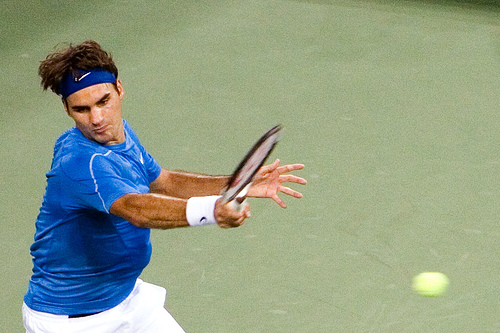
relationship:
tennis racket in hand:
[220, 123, 283, 213] [216, 197, 251, 229]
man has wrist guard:
[21, 37, 307, 333] [186, 193, 224, 227]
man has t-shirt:
[21, 37, 307, 333] [22, 118, 160, 317]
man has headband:
[21, 37, 307, 333] [58, 66, 115, 99]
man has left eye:
[21, 37, 307, 333] [99, 98, 108, 105]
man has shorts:
[21, 37, 307, 333] [22, 278, 187, 333]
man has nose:
[21, 37, 307, 333] [92, 105, 104, 125]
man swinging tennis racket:
[21, 37, 307, 333] [220, 123, 283, 213]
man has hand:
[21, 37, 307, 333] [216, 197, 251, 229]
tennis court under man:
[0, 1, 499, 333] [21, 37, 307, 333]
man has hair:
[21, 37, 307, 333] [39, 39, 117, 95]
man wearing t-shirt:
[21, 37, 307, 333] [22, 118, 160, 317]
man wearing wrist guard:
[21, 37, 307, 333] [186, 193, 224, 227]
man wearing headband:
[21, 37, 307, 333] [58, 66, 115, 99]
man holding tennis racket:
[21, 37, 307, 333] [220, 123, 283, 213]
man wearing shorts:
[21, 37, 307, 333] [22, 278, 187, 333]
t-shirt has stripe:
[22, 118, 160, 317] [89, 149, 113, 215]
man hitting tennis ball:
[21, 37, 307, 333] [412, 271, 450, 297]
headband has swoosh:
[58, 66, 115, 99] [74, 71, 92, 82]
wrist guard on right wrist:
[186, 193, 224, 227] [198, 196, 217, 225]